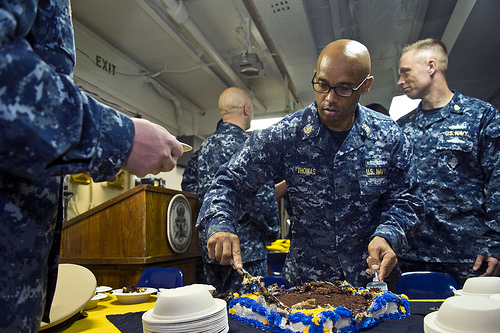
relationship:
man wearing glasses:
[190, 36, 418, 305] [310, 69, 368, 99]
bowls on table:
[141, 284, 226, 324] [43, 293, 158, 332]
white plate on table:
[36, 262, 98, 331] [29, 285, 499, 330]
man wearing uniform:
[11, 11, 160, 320] [180, 121, 280, 266]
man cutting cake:
[190, 36, 418, 305] [217, 269, 409, 331]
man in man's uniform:
[0, 0, 183, 332] [193, 100, 426, 288]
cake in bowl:
[119, 284, 141, 294] [116, 281, 161, 316]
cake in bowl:
[226, 282, 404, 332] [116, 281, 161, 316]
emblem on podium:
[165, 193, 193, 254] [61, 184, 196, 286]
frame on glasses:
[308, 80, 360, 101] [306, 67, 374, 104]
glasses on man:
[306, 67, 374, 104] [194, 39, 422, 285]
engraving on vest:
[282, 153, 342, 190] [261, 113, 405, 240]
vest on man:
[261, 113, 405, 240] [191, 47, 482, 305]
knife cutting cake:
[229, 253, 289, 310] [223, 278, 409, 331]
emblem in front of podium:
[162, 188, 195, 257] [58, 180, 208, 285]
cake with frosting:
[226, 282, 404, 332] [265, 270, 372, 310]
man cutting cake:
[190, 36, 418, 305] [249, 284, 405, 330]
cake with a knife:
[249, 284, 405, 330] [234, 262, 284, 308]